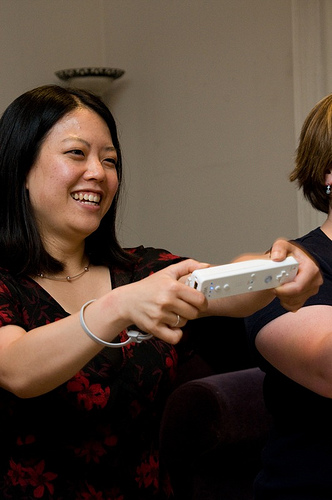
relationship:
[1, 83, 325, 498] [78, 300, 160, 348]
woman wearing strap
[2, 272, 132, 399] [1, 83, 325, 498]
arm of woman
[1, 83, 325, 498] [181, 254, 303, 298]
woman holding controller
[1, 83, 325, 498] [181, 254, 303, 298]
woman gripping controller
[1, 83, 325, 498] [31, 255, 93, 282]
woman wearing necklace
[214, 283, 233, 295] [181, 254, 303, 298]
buttons of controller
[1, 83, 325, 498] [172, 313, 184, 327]
woman wearing ring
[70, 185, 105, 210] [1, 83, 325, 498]
mouth of woman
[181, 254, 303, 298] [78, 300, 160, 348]
controller with strap